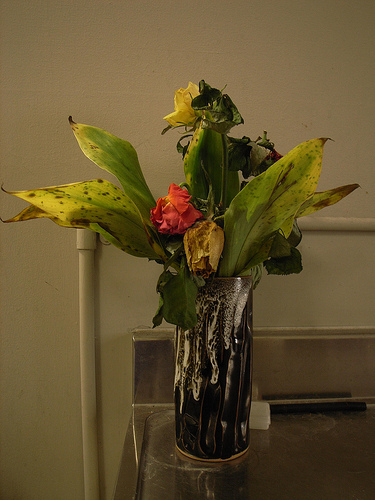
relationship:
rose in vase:
[152, 183, 207, 234] [174, 273, 252, 463]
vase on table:
[174, 273, 252, 463] [112, 326, 374, 499]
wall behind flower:
[2, 2, 374, 79] [2, 79, 360, 330]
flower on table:
[2, 79, 360, 330] [112, 326, 374, 499]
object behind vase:
[270, 401, 368, 414] [174, 273, 252, 463]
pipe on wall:
[76, 227, 102, 500] [2, 2, 374, 79]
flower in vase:
[2, 79, 360, 330] [174, 273, 252, 463]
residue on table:
[272, 412, 335, 441] [112, 326, 374, 499]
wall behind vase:
[2, 2, 374, 79] [174, 273, 252, 463]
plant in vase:
[2, 79, 360, 330] [174, 273, 252, 463]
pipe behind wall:
[76, 227, 102, 500] [2, 2, 374, 79]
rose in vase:
[183, 219, 225, 275] [174, 273, 252, 463]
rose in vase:
[163, 82, 200, 129] [174, 273, 252, 463]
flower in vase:
[152, 183, 207, 234] [174, 273, 252, 463]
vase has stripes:
[174, 273, 252, 463] [196, 317, 212, 455]